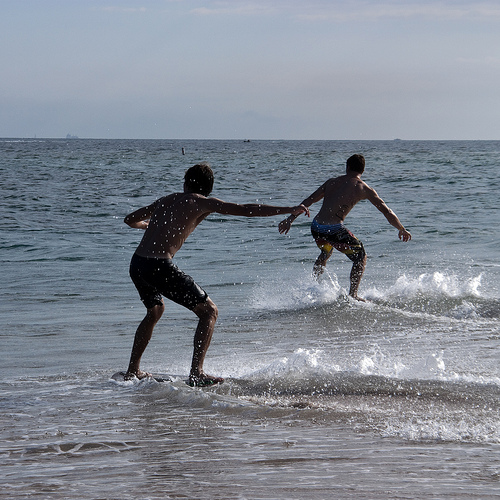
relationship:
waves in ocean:
[210, 253, 439, 445] [9, 144, 456, 483]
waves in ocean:
[210, 253, 439, 445] [38, 122, 461, 485]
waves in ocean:
[210, 253, 439, 445] [45, 171, 497, 489]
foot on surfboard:
[118, 357, 161, 387] [105, 366, 263, 400]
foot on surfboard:
[170, 360, 239, 400] [105, 366, 263, 400]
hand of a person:
[272, 208, 299, 240] [316, 144, 388, 229]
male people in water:
[123, 162, 307, 386] [10, 133, 477, 438]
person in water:
[277, 153, 413, 302] [10, 133, 477, 438]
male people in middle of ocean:
[123, 162, 307, 386] [38, 122, 461, 485]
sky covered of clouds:
[19, 15, 499, 160] [174, 24, 281, 111]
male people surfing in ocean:
[123, 162, 307, 386] [58, 177, 443, 420]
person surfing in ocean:
[310, 131, 413, 243] [58, 177, 443, 420]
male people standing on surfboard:
[123, 162, 307, 386] [101, 359, 279, 404]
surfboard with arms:
[101, 359, 279, 404] [192, 175, 337, 227]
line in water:
[12, 175, 82, 216] [1, 155, 146, 305]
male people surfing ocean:
[123, 162, 307, 386] [39, 173, 477, 463]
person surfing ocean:
[277, 153, 413, 302] [39, 173, 477, 463]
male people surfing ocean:
[123, 162, 307, 386] [23, 144, 484, 431]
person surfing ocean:
[277, 153, 413, 302] [23, 144, 484, 431]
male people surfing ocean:
[123, 162, 307, 386] [0, 251, 498, 496]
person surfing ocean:
[277, 153, 413, 302] [0, 251, 498, 496]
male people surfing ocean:
[123, 162, 307, 386] [28, 150, 495, 475]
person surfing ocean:
[277, 153, 413, 302] [28, 150, 495, 475]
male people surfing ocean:
[123, 162, 307, 386] [5, 139, 499, 442]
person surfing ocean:
[277, 153, 413, 302] [5, 139, 499, 442]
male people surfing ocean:
[123, 162, 307, 386] [79, 151, 462, 496]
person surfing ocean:
[277, 153, 413, 302] [79, 151, 462, 496]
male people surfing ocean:
[123, 162, 307, 386] [1, 151, 493, 409]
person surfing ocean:
[277, 153, 413, 302] [1, 151, 493, 409]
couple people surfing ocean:
[124, 154, 412, 387] [9, 144, 456, 483]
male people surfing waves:
[123, 162, 307, 386] [104, 253, 464, 402]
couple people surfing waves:
[124, 154, 412, 387] [139, 272, 456, 402]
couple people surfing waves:
[103, 149, 415, 415] [141, 276, 471, 416]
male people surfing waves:
[123, 150, 417, 398] [142, 271, 473, 431]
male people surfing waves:
[123, 162, 307, 386] [140, 264, 470, 422]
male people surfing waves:
[123, 162, 307, 386] [123, 267, 472, 400]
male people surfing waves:
[123, 162, 307, 386] [170, 260, 465, 420]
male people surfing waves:
[123, 162, 307, 386] [139, 272, 456, 402]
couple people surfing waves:
[124, 154, 412, 387] [140, 250, 453, 423]